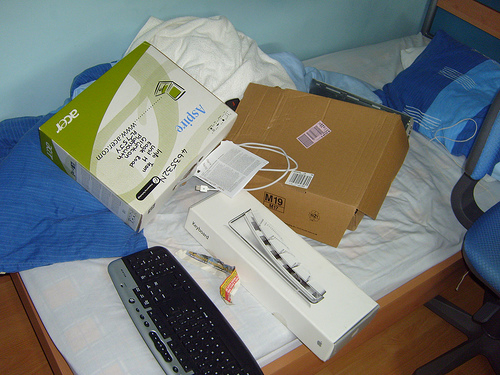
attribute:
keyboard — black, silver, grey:
[107, 244, 265, 373]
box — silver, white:
[187, 183, 382, 362]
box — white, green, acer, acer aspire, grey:
[38, 39, 239, 230]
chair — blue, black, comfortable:
[451, 89, 497, 303]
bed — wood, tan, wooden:
[263, 251, 463, 374]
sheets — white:
[134, 19, 466, 348]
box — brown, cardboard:
[219, 81, 413, 247]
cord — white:
[192, 140, 304, 202]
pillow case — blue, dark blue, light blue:
[370, 29, 499, 157]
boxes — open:
[35, 42, 411, 360]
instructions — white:
[191, 140, 270, 198]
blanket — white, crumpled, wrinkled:
[131, 17, 301, 98]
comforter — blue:
[2, 116, 152, 272]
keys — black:
[130, 255, 174, 286]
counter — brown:
[1, 268, 61, 371]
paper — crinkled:
[179, 246, 240, 309]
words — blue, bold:
[173, 103, 207, 133]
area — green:
[37, 42, 149, 169]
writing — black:
[115, 131, 188, 188]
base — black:
[413, 297, 498, 374]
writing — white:
[51, 106, 84, 134]